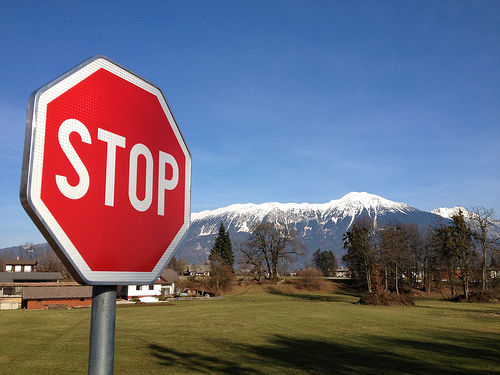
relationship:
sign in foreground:
[21, 59, 194, 374] [3, 209, 498, 375]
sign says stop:
[21, 59, 194, 374] [57, 118, 180, 219]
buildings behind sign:
[1, 254, 217, 308] [21, 59, 194, 374]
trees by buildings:
[207, 209, 498, 305] [1, 254, 217, 308]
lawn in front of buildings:
[7, 294, 499, 374] [1, 254, 217, 308]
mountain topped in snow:
[1, 187, 499, 271] [200, 191, 408, 219]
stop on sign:
[57, 118, 180, 219] [21, 59, 194, 374]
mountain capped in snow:
[1, 187, 499, 271] [200, 191, 408, 219]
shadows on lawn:
[145, 326, 499, 373] [7, 294, 499, 374]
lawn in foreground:
[7, 294, 499, 374] [3, 209, 498, 375]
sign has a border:
[21, 59, 194, 374] [33, 58, 48, 233]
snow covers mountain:
[200, 191, 408, 219] [1, 187, 499, 271]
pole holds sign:
[88, 287, 119, 374] [21, 59, 194, 374]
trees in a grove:
[207, 209, 498, 305] [341, 213, 499, 309]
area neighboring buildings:
[300, 254, 500, 293] [321, 263, 499, 281]